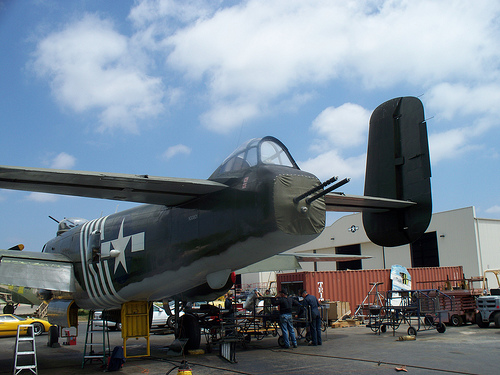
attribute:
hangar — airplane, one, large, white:
[291, 205, 499, 309]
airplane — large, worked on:
[51, 172, 334, 304]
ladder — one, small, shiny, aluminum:
[12, 321, 48, 373]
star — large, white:
[109, 215, 131, 274]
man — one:
[270, 285, 300, 352]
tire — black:
[437, 323, 447, 335]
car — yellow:
[0, 312, 51, 334]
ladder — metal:
[11, 322, 42, 373]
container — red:
[277, 266, 466, 321]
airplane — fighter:
[46, 68, 476, 343]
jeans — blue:
[278, 315, 299, 347]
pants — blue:
[309, 307, 321, 341]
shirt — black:
[277, 293, 297, 312]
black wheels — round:
[405, 326, 418, 336]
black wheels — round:
[379, 325, 386, 333]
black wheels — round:
[434, 321, 446, 333]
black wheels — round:
[448, 313, 463, 328]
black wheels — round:
[423, 314, 435, 326]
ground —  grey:
[0, 325, 499, 371]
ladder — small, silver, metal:
[7, 316, 60, 371]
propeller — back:
[37, 194, 95, 265]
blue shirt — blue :
[301, 295, 322, 312]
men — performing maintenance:
[261, 265, 345, 345]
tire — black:
[30, 325, 42, 335]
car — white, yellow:
[1, 309, 54, 341]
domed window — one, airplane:
[218, 135, 293, 170]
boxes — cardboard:
[324, 298, 348, 321]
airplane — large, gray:
[65, 116, 382, 318]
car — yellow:
[1, 310, 57, 339]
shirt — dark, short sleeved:
[272, 296, 294, 315]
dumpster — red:
[302, 265, 458, 314]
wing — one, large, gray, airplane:
[0, 158, 219, 216]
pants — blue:
[272, 311, 344, 353]